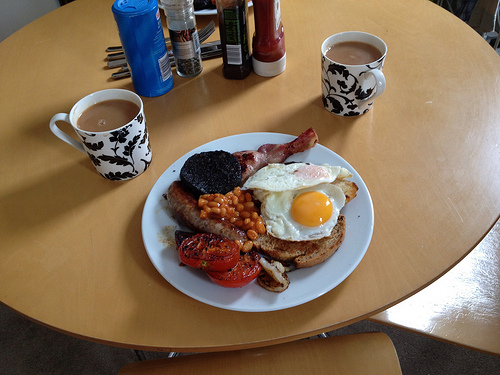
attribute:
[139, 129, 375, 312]
plate — white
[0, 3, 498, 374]
table — round, tan, wooden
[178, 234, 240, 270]
tomato — fried, red, seasoned, grilled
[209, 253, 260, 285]
tomato — fried, red, seasoned, grilled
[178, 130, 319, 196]
sausage — fat, big, round, one, patty, burnt, grilled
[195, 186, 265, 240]
beans — brown, baked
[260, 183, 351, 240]
egg — fried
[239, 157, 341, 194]
egg — fried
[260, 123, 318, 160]
bacon — sliced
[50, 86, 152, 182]
cup — white, black, blacky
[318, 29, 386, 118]
cup — white, blacky, black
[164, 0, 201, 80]
pepper — black, spice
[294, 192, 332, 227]
yolk up — yellow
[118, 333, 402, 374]
chair — wooden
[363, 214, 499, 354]
chair — wooden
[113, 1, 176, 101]
salt shaker — blue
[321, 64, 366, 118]
pattern — floral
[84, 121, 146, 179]
pattern — floral